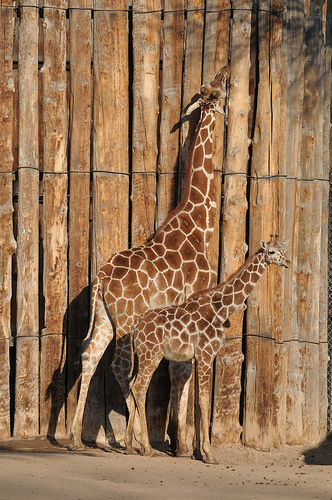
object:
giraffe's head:
[186, 63, 238, 118]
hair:
[184, 242, 266, 300]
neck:
[190, 248, 271, 312]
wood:
[251, 0, 332, 448]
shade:
[144, 2, 331, 123]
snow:
[202, 453, 264, 495]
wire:
[3, 3, 332, 19]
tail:
[83, 275, 100, 354]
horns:
[198, 84, 222, 101]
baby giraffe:
[114, 230, 293, 460]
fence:
[0, 0, 332, 445]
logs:
[131, 1, 157, 224]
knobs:
[238, 105, 248, 121]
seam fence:
[0, 160, 331, 200]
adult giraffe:
[68, 65, 230, 456]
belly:
[163, 350, 192, 363]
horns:
[268, 234, 279, 243]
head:
[259, 228, 300, 271]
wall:
[1, 1, 332, 444]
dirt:
[0, 436, 331, 497]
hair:
[126, 227, 293, 460]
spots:
[197, 300, 216, 321]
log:
[10, 0, 40, 440]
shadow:
[300, 431, 330, 467]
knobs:
[217, 349, 248, 367]